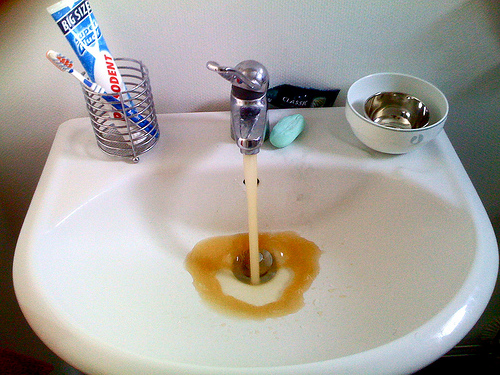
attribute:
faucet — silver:
[202, 41, 271, 153]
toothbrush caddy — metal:
[76, 57, 163, 163]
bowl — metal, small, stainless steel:
[362, 89, 432, 131]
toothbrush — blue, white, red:
[45, 48, 158, 138]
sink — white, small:
[8, 94, 498, 373]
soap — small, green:
[267, 112, 305, 147]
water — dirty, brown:
[183, 221, 332, 309]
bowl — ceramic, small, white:
[342, 68, 454, 158]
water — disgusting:
[182, 150, 323, 324]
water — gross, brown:
[184, 139, 318, 324]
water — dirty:
[233, 147, 267, 292]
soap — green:
[247, 97, 327, 159]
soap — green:
[266, 110, 308, 150]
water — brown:
[184, 155, 326, 317]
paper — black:
[267, 85, 339, 110]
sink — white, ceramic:
[53, 159, 498, 353]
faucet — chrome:
[202, 45, 275, 158]